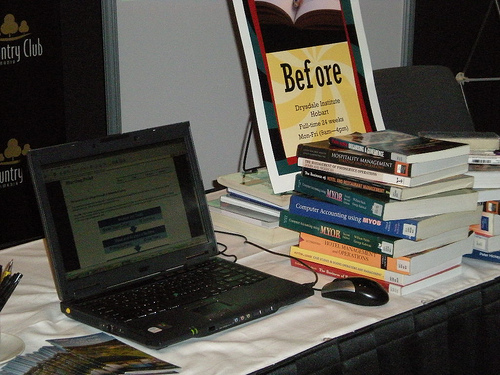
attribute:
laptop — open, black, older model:
[21, 117, 318, 351]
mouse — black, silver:
[319, 273, 392, 309]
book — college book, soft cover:
[284, 242, 465, 287]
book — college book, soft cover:
[275, 206, 473, 262]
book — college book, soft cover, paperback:
[286, 190, 485, 243]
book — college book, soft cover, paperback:
[297, 163, 477, 203]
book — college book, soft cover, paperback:
[327, 125, 472, 166]